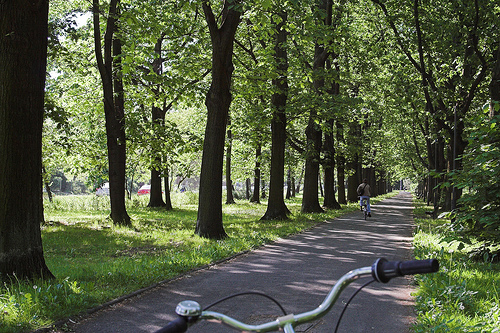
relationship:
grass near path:
[97, 226, 167, 279] [308, 203, 415, 263]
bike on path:
[238, 252, 418, 324] [308, 203, 415, 263]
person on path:
[352, 177, 378, 221] [308, 203, 415, 263]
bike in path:
[238, 252, 418, 324] [308, 203, 415, 263]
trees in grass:
[185, 5, 315, 236] [97, 226, 167, 279]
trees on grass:
[185, 5, 315, 236] [97, 226, 167, 279]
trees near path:
[185, 5, 315, 236] [308, 203, 415, 263]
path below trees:
[308, 203, 415, 263] [185, 5, 315, 236]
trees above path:
[185, 5, 315, 236] [308, 203, 415, 263]